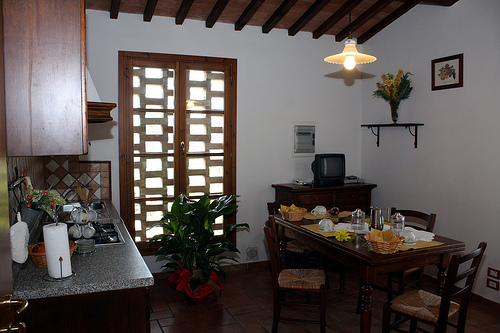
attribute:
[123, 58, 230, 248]
window — framed, wood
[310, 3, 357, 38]
rafter — black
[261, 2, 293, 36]
rafter — black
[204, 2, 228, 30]
rafter — black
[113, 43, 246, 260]
window — large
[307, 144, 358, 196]
t.v — small, black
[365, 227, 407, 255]
basket — small, brown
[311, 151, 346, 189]
tv — black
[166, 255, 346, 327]
floor — tiled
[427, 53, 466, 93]
picture — small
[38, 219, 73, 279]
papertowel — roll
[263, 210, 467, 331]
table — dining, room, set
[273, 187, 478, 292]
table — buffet table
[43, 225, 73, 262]
paper towel — white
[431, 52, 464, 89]
picture — framed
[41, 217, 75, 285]
paper towels — roll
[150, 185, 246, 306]
plant — green, large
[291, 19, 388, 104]
light — overhead